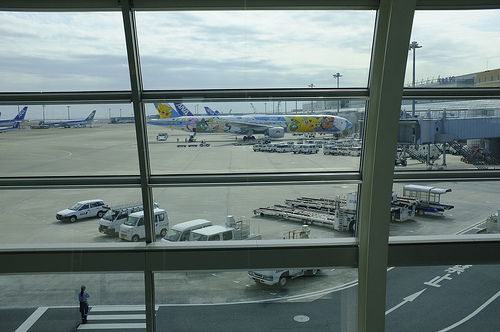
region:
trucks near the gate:
[260, 197, 361, 232]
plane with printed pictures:
[157, 111, 339, 138]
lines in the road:
[386, 269, 458, 303]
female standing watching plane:
[73, 277, 95, 331]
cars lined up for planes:
[63, 194, 235, 244]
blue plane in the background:
[30, 112, 116, 132]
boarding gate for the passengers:
[403, 114, 493, 149]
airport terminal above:
[313, 75, 497, 102]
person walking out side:
[71, 282, 93, 320]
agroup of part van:
[95, 199, 237, 246]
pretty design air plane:
[143, 102, 357, 138]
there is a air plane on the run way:
[25, 107, 98, 132]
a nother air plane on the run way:
[0, 105, 27, 135]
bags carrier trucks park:
[255, 174, 450, 229]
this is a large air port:
[0, 72, 498, 327]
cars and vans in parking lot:
[48, 184, 333, 295]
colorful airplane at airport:
[149, 101, 354, 150]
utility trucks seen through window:
[251, 179, 465, 236]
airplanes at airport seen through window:
[28, 84, 355, 161]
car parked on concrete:
[51, 195, 108, 225]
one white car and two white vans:
[55, 196, 175, 242]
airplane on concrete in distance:
[34, 108, 101, 134]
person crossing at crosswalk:
[73, 282, 97, 327]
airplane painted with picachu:
[147, 101, 359, 145]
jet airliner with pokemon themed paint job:
[148, 102, 360, 151]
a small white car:
[55, 198, 105, 224]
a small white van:
[123, 205, 166, 244]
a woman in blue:
[78, 283, 92, 320]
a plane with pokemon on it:
[144, 99, 354, 139]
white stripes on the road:
[78, 302, 158, 330]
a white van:
[99, 202, 159, 236]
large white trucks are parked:
[254, 193, 411, 233]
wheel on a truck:
[279, 274, 288, 286]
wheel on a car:
[68, 215, 74, 221]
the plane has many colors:
[149, 96, 351, 143]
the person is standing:
[80, 284, 89, 319]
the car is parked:
[117, 207, 167, 243]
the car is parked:
[97, 200, 159, 235]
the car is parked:
[58, 197, 106, 217]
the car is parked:
[160, 218, 209, 243]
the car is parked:
[189, 224, 233, 241]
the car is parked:
[248, 267, 321, 289]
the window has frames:
[1, 7, 498, 329]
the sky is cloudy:
[5, 11, 498, 123]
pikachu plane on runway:
[148, 106, 345, 141]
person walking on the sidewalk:
[67, 278, 102, 320]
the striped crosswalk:
[84, 304, 159, 329]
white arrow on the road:
[380, 285, 427, 314]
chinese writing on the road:
[425, 266, 472, 291]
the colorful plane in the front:
[145, 105, 352, 141]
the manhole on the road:
[292, 308, 316, 329]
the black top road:
[12, 267, 491, 328]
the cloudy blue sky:
[5, 19, 489, 115]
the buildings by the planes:
[306, 70, 498, 152]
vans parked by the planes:
[240, 137, 390, 157]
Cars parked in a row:
[56, 193, 171, 244]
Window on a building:
[149, 180, 359, 240]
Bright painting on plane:
[140, 88, 363, 140]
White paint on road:
[93, 305, 128, 330]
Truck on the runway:
[255, 203, 365, 234]